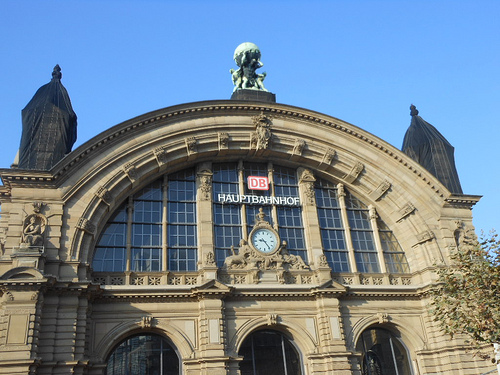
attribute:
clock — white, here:
[248, 224, 280, 256]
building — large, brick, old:
[1, 40, 497, 374]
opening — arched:
[234, 323, 306, 374]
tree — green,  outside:
[428, 222, 499, 369]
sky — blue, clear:
[0, 2, 499, 270]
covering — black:
[15, 60, 80, 169]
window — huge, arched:
[89, 157, 414, 276]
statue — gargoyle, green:
[227, 40, 278, 101]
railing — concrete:
[89, 272, 417, 289]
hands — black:
[253, 238, 272, 248]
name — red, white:
[215, 193, 300, 206]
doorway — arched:
[105, 332, 180, 374]